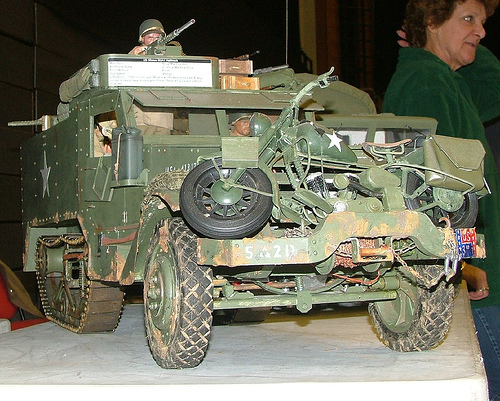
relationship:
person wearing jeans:
[379, 1, 499, 398] [481, 312, 496, 347]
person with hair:
[379, 1, 499, 398] [406, 0, 499, 64]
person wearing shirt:
[379, 1, 499, 398] [383, 45, 480, 147]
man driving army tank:
[229, 110, 254, 138] [14, 16, 489, 369]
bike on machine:
[180, 67, 480, 277] [61, 70, 166, 270]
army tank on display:
[14, 16, 489, 369] [1, 16, 491, 398]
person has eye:
[379, 1, 499, 386] [454, 8, 476, 26]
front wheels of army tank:
[141, 212, 452, 368] [14, 16, 489, 369]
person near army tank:
[379, 1, 499, 398] [14, 16, 489, 369]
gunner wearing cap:
[120, 14, 193, 61] [134, 17, 165, 42]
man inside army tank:
[229, 110, 254, 138] [14, 16, 489, 369]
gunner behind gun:
[120, 14, 193, 61] [132, 14, 197, 55]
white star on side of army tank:
[29, 145, 66, 190] [14, 16, 489, 369]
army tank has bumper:
[14, 16, 489, 369] [192, 203, 484, 290]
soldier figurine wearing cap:
[129, 18, 183, 55] [134, 17, 168, 41]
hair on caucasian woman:
[399, 1, 490, 48] [411, 2, 493, 89]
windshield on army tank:
[127, 90, 305, 135] [14, 16, 489, 369]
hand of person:
[452, 261, 493, 301] [387, 10, 498, 333]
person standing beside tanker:
[379, 1, 499, 398] [7, 14, 490, 369]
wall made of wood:
[0, 0, 311, 267] [0, 0, 299, 305]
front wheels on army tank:
[141, 212, 218, 371] [14, 16, 489, 369]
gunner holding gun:
[120, 14, 193, 61] [138, 20, 198, 52]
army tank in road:
[14, 16, 489, 369] [1, 279, 491, 399]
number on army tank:
[245, 237, 308, 264] [14, 16, 489, 369]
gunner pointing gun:
[120, 14, 193, 61] [134, 20, 197, 55]